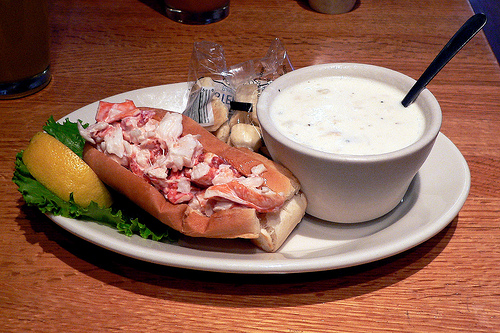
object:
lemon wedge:
[22, 131, 113, 211]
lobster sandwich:
[78, 95, 307, 253]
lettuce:
[11, 115, 182, 241]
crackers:
[183, 76, 262, 152]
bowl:
[255, 60, 442, 224]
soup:
[269, 75, 427, 157]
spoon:
[400, 12, 487, 109]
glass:
[0, 0, 53, 100]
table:
[0, 0, 500, 332]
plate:
[29, 77, 470, 275]